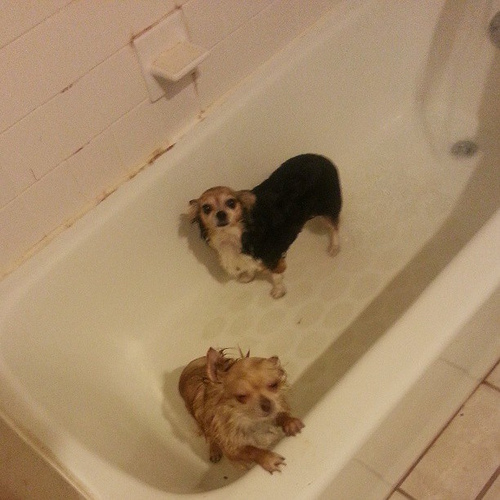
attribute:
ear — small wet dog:
[270, 354, 279, 366]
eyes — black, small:
[194, 197, 247, 217]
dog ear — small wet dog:
[203, 347, 229, 382]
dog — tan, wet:
[191, 160, 342, 280]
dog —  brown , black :
[173, 349, 288, 469]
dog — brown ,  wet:
[162, 342, 316, 481]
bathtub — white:
[5, 5, 499, 494]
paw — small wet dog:
[283, 415, 303, 442]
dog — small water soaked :
[179, 352, 286, 439]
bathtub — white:
[279, 74, 486, 404]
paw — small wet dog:
[269, 278, 289, 295]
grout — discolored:
[116, 134, 184, 194]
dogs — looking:
[149, 135, 369, 476]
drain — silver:
[428, 121, 498, 168]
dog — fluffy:
[187, 145, 360, 297]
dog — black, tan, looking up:
[186, 147, 352, 307]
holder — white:
[98, 17, 262, 96]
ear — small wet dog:
[198, 361, 222, 402]